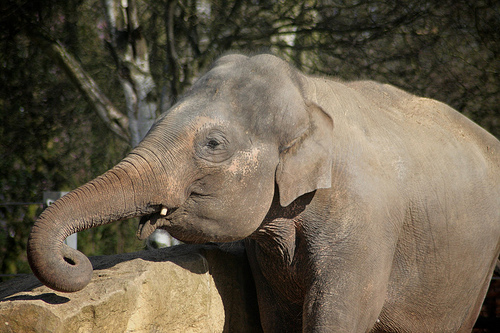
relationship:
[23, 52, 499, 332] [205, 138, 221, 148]
elephant has eye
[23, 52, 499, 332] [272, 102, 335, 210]
elephant has ear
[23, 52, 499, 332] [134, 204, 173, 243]
elephant has mouth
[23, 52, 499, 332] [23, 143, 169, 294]
elephant has trunk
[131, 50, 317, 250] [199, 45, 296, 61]
head has hair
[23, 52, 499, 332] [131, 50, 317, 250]
elephant has head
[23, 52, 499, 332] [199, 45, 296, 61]
elephant has hair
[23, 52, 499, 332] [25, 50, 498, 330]
elephant has skin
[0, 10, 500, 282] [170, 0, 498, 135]
tree has branches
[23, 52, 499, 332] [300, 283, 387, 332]
elephant has leg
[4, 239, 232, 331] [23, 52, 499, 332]
rock behind elephant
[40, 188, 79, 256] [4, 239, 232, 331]
pole behind rock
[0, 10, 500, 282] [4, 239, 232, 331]
tree behind rock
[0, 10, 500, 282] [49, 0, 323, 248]
tree has bark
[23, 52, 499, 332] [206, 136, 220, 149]
elephant has eyes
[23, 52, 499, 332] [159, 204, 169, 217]
elephant has tusk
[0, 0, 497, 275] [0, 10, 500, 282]
building behind tree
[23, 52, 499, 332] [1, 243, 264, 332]
elephant casting shadow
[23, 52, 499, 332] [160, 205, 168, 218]
elephant has tooth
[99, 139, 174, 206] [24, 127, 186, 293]
wrinkles on trunk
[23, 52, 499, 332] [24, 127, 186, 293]
elephant has trunk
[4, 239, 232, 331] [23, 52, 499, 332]
rock by elephant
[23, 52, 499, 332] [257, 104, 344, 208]
elephant has ear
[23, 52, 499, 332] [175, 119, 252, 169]
elephant has eye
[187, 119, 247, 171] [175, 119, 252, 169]
wrinkles around eye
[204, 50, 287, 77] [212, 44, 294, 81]
hair on mups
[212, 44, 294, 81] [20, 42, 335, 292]
mups on head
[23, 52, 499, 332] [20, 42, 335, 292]
elephant has head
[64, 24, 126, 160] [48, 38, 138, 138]
moss on branch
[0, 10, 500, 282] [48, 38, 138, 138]
tree has branch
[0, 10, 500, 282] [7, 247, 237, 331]
tree behind wall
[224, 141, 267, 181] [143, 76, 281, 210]
marks on face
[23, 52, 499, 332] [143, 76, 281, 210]
elephant has face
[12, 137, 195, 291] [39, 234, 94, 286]
trunk has bottom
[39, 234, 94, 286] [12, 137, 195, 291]
bottom curled under trunk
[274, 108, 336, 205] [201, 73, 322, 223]
ear on side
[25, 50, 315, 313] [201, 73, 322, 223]
head has side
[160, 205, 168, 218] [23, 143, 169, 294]
tooth on side of trunk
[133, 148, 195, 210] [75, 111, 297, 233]
spots on skin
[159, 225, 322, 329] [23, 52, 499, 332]
shadow from elephant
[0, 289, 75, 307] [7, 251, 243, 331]
shadow on rock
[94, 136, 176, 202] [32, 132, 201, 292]
lines on trunk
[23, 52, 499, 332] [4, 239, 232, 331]
elephant near rock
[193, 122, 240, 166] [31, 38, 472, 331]
eye on elephant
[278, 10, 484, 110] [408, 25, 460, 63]
tree has leaves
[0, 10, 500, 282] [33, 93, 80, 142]
tree has leaves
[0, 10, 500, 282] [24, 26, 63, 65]
tree has leaves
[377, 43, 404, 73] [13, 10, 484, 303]
leaves of tree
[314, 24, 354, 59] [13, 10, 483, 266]
leaves of tree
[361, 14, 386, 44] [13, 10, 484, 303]
leaves of tree